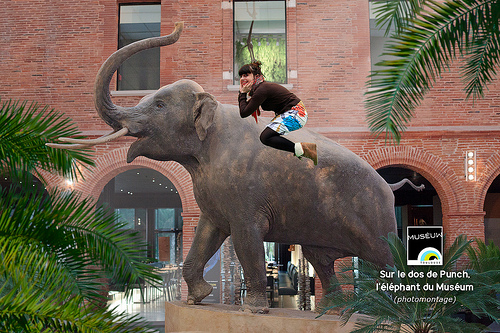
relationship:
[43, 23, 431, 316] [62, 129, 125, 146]
statue has tusk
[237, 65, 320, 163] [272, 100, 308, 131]
woman wearing shorts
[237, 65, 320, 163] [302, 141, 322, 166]
woman wearing boots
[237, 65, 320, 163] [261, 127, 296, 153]
woman wearing leggings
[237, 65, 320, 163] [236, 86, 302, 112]
woman wearing shirt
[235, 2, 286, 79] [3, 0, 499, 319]
window on building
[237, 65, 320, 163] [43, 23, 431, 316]
woman sitting on top of statue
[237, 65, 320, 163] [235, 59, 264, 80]
woman has hair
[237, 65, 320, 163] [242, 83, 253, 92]
woman has hand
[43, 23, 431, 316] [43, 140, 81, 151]
statue has tusk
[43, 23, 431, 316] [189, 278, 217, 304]
statue has foot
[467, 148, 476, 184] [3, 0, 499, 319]
light on side of building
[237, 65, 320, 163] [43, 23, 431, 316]
woman on top of statue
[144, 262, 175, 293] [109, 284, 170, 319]
table on top of floor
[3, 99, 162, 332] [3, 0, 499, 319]
tree in front of building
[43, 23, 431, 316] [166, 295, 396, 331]
statue on top of block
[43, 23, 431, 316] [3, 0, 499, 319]
statue in front of building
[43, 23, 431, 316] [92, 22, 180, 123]
statue has trunk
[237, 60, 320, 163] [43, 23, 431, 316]
woman on statue